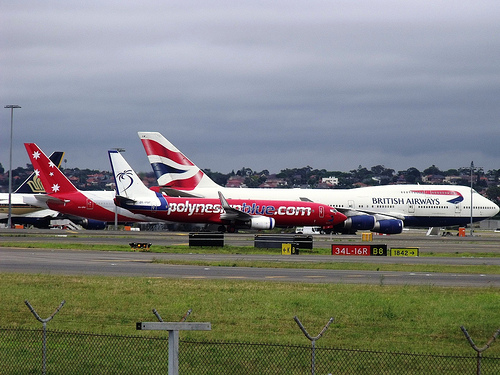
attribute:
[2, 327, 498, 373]
fence — metal, link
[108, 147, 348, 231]
jet — red, white, blue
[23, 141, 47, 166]
stars — white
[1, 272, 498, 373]
grass — green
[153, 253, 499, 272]
grass — green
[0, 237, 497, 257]
grass — green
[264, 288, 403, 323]
grass — green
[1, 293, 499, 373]
fence — tall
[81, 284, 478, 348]
field — grassy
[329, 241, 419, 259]
markers — traffic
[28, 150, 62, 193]
stars — white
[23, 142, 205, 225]
plane — parked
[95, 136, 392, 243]
jet airliner — red, white, blue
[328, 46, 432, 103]
sky — cloudy, grey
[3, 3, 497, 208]
sky — cloudy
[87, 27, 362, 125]
clouds — dark gray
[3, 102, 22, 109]
light — tall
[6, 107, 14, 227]
pole — grey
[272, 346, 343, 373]
fence — metal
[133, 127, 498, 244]
airplane — white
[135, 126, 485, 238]
airliner — red, white, blue, jet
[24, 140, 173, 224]
airliner — black, white, yellow, jet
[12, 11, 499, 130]
clouds — gray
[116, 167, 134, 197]
tree — palm